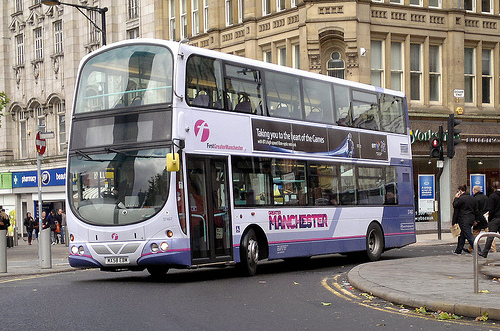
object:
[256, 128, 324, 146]
words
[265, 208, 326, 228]
words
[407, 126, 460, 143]
words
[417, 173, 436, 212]
words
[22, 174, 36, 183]
words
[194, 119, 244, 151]
advertisement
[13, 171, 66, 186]
advertisement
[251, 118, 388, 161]
advertisement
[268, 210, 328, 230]
advertisement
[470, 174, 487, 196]
advertisement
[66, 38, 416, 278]
bus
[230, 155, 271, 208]
window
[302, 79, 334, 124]
window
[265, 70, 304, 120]
window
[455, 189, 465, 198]
cellphone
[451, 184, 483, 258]
woman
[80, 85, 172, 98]
object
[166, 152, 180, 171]
mirror cover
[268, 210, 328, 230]
manchester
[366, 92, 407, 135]
window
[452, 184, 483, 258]
lady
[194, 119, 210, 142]
logo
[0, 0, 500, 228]
building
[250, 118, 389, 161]
sign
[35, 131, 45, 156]
sign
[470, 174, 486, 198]
sign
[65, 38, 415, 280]
double-decker bus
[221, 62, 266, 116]
glass window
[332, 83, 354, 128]
window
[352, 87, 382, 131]
window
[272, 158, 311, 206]
window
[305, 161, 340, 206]
window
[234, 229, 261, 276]
tire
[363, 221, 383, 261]
tire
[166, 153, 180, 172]
mirror